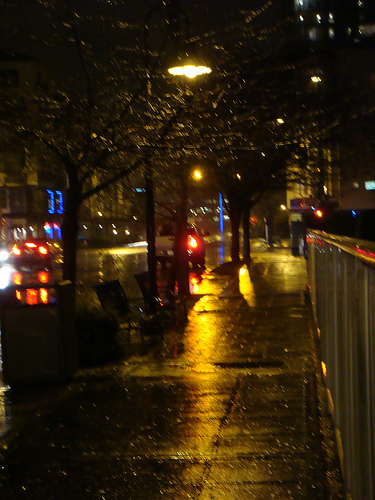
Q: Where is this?
A: This is at the city.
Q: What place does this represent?
A: It represents the city.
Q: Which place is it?
A: It is a city.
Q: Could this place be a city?
A: Yes, it is a city.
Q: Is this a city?
A: Yes, it is a city.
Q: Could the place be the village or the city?
A: It is the city.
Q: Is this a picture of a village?
A: No, the picture is showing a city.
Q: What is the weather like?
A: It is rainy.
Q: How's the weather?
A: It is rainy.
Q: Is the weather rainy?
A: Yes, it is rainy.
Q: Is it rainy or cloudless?
A: It is rainy.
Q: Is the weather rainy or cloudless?
A: It is rainy.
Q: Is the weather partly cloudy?
A: No, it is rainy.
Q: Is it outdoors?
A: Yes, it is outdoors.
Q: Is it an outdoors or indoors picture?
A: It is outdoors.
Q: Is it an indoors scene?
A: No, it is outdoors.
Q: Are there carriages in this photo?
A: No, there are no carriages.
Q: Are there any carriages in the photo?
A: No, there are no carriages.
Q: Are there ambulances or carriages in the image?
A: No, there are no carriages or ambulances.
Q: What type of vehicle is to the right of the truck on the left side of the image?
A: The vehicle is a car.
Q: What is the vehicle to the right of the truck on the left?
A: The vehicle is a car.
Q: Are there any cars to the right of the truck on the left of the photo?
A: Yes, there is a car to the right of the truck.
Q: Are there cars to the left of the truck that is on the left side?
A: No, the car is to the right of the truck.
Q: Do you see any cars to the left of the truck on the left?
A: No, the car is to the right of the truck.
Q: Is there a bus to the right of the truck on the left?
A: No, there is a car to the right of the truck.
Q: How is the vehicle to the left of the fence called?
A: The vehicle is a car.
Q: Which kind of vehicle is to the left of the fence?
A: The vehicle is a car.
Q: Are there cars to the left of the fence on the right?
A: Yes, there is a car to the left of the fence.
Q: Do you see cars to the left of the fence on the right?
A: Yes, there is a car to the left of the fence.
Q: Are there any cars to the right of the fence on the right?
A: No, the car is to the left of the fence.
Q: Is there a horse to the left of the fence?
A: No, there is a car to the left of the fence.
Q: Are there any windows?
A: Yes, there is a window.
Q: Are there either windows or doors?
A: Yes, there is a window.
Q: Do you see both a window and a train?
A: No, there is a window but no trains.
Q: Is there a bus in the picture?
A: No, there are no buses.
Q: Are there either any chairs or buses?
A: No, there are no buses or chairs.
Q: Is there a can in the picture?
A: Yes, there is a can.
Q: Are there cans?
A: Yes, there is a can.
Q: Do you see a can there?
A: Yes, there is a can.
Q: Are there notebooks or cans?
A: Yes, there is a can.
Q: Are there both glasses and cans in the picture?
A: No, there is a can but no glasses.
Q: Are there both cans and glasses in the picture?
A: No, there is a can but no glasses.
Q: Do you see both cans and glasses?
A: No, there is a can but no glasses.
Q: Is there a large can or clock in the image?
A: Yes, there is a large can.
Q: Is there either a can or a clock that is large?
A: Yes, the can is large.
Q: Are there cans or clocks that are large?
A: Yes, the can is large.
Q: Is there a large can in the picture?
A: Yes, there is a large can.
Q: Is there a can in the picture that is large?
A: Yes, there is a can that is large.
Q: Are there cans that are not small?
A: Yes, there is a large can.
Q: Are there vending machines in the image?
A: No, there are no vending machines.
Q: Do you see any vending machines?
A: No, there are no vending machines.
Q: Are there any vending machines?
A: No, there are no vending machines.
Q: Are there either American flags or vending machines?
A: No, there are no vending machines or American flags.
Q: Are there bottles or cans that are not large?
A: No, there is a can but it is large.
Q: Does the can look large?
A: Yes, the can is large.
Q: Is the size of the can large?
A: Yes, the can is large.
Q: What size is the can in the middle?
A: The can is large.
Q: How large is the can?
A: The can is large.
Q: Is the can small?
A: No, the can is large.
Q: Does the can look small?
A: No, the can is large.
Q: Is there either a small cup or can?
A: No, there is a can but it is large.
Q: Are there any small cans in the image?
A: No, there is a can but it is large.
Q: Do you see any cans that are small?
A: No, there is a can but it is large.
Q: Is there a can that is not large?
A: No, there is a can but it is large.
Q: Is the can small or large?
A: The can is large.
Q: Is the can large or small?
A: The can is large.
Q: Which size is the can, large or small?
A: The can is large.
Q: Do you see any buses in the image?
A: No, there are no buses.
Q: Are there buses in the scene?
A: No, there are no buses.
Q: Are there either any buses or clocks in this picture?
A: No, there are no buses or clocks.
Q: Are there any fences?
A: Yes, there is a fence.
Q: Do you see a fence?
A: Yes, there is a fence.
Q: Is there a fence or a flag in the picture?
A: Yes, there is a fence.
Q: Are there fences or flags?
A: Yes, there is a fence.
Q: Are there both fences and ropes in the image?
A: No, there is a fence but no ropes.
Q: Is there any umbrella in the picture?
A: No, there are no umbrellas.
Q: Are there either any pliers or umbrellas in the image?
A: No, there are no umbrellas or pliers.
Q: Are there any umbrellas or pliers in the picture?
A: No, there are no umbrellas or pliers.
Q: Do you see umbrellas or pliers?
A: No, there are no umbrellas or pliers.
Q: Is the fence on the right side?
A: Yes, the fence is on the right of the image.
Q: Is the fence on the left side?
A: No, the fence is on the right of the image.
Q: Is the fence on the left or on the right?
A: The fence is on the right of the image.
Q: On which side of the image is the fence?
A: The fence is on the right of the image.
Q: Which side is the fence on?
A: The fence is on the right of the image.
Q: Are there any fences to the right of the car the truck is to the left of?
A: Yes, there is a fence to the right of the car.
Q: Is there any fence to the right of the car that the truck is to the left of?
A: Yes, there is a fence to the right of the car.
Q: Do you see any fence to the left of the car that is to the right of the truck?
A: No, the fence is to the right of the car.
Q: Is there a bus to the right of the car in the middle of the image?
A: No, there is a fence to the right of the car.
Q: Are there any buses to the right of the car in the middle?
A: No, there is a fence to the right of the car.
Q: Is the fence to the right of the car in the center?
A: Yes, the fence is to the right of the car.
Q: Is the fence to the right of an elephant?
A: No, the fence is to the right of the car.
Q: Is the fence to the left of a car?
A: No, the fence is to the right of a car.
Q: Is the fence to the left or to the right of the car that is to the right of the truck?
A: The fence is to the right of the car.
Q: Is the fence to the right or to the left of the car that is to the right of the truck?
A: The fence is to the right of the car.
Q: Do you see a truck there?
A: Yes, there is a truck.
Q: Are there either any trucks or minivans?
A: Yes, there is a truck.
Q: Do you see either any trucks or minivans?
A: Yes, there is a truck.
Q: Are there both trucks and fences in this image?
A: Yes, there are both a truck and a fence.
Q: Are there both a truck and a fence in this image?
A: Yes, there are both a truck and a fence.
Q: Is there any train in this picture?
A: No, there are no trains.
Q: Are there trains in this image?
A: No, there are no trains.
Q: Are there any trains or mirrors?
A: No, there are no trains or mirrors.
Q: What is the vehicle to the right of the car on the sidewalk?
A: The vehicle is a truck.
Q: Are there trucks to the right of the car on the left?
A: Yes, there is a truck to the right of the car.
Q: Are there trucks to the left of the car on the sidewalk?
A: No, the truck is to the right of the car.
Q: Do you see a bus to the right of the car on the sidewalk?
A: No, there is a truck to the right of the car.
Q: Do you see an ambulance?
A: No, there are no ambulances.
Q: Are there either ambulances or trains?
A: No, there are no ambulances or trains.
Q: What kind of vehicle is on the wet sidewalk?
A: The vehicle is a car.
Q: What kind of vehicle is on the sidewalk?
A: The vehicle is a car.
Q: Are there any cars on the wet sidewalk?
A: Yes, there is a car on the sidewalk.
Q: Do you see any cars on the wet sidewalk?
A: Yes, there is a car on the sidewalk.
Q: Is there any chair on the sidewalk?
A: No, there is a car on the sidewalk.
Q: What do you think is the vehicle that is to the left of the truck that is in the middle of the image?
A: The vehicle is a car.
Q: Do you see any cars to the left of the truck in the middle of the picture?
A: Yes, there is a car to the left of the truck.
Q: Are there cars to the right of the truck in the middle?
A: No, the car is to the left of the truck.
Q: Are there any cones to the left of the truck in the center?
A: No, there is a car to the left of the truck.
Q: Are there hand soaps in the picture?
A: No, there are no hand soaps.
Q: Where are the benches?
A: The benches are on the sidewalk.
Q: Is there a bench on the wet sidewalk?
A: Yes, there are benches on the sidewalk.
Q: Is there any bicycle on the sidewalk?
A: No, there are benches on the sidewalk.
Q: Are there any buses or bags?
A: No, there are no buses or bags.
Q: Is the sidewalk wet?
A: Yes, the sidewalk is wet.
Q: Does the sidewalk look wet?
A: Yes, the sidewalk is wet.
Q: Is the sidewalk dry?
A: No, the sidewalk is wet.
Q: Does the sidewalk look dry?
A: No, the sidewalk is wet.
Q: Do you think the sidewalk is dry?
A: No, the sidewalk is wet.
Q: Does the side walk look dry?
A: No, the side walk is wet.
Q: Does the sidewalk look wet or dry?
A: The sidewalk is wet.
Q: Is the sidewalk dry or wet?
A: The sidewalk is wet.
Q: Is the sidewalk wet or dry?
A: The sidewalk is wet.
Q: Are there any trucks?
A: Yes, there is a truck.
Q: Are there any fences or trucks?
A: Yes, there is a truck.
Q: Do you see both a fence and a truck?
A: Yes, there are both a truck and a fence.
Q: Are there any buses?
A: No, there are no buses.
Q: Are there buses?
A: No, there are no buses.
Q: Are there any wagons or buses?
A: No, there are no buses or wagons.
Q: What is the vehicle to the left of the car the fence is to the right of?
A: The vehicle is a truck.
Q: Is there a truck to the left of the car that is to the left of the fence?
A: Yes, there is a truck to the left of the car.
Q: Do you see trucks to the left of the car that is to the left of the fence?
A: Yes, there is a truck to the left of the car.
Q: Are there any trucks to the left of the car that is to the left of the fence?
A: Yes, there is a truck to the left of the car.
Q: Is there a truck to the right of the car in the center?
A: No, the truck is to the left of the car.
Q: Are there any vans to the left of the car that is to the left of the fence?
A: No, there is a truck to the left of the car.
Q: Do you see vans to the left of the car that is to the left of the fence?
A: No, there is a truck to the left of the car.